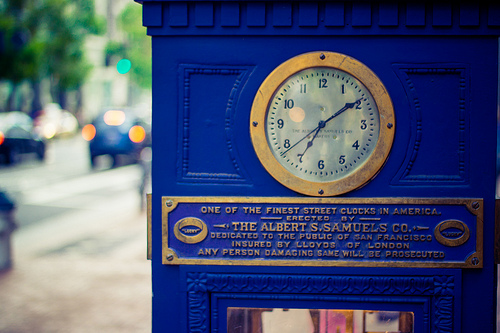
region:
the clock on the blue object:
[248, 50, 393, 195]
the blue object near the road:
[134, 0, 497, 331]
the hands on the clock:
[280, 95, 364, 162]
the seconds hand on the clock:
[281, 121, 320, 154]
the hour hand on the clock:
[301, 127, 323, 155]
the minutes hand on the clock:
[318, 94, 363, 127]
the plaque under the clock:
[161, 193, 485, 268]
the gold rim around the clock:
[248, 50, 395, 196]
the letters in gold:
[196, 203, 446, 260]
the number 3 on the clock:
[359, 117, 367, 129]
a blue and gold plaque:
[159, 193, 489, 270]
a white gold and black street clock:
[247, 47, 399, 197]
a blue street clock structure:
[136, 0, 496, 331]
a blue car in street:
[85, 108, 146, 164]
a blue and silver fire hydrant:
[0, 190, 20, 273]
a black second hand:
[279, 120, 324, 157]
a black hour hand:
[298, 120, 321, 156]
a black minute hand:
[316, 98, 354, 124]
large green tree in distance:
[1, 0, 98, 105]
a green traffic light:
[116, 58, 135, 73]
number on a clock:
[336, 75, 351, 100]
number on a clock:
[352, 110, 375, 132]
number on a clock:
[345, 136, 362, 152]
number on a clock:
[335, 147, 355, 169]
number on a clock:
[313, 148, 331, 183]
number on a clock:
[292, 146, 312, 168]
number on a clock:
[281, 133, 294, 155]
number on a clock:
[270, 111, 293, 131]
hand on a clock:
[318, 91, 358, 124]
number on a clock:
[307, 68, 337, 95]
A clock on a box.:
[265, 66, 380, 182]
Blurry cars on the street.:
[0, 101, 152, 168]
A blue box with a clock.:
[134, 0, 497, 332]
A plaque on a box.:
[161, 195, 485, 270]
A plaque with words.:
[159, 195, 484, 270]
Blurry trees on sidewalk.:
[3, 1, 164, 125]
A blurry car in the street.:
[88, 108, 151, 170]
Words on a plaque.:
[160, 195, 485, 269]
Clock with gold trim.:
[248, 50, 397, 195]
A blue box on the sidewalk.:
[133, 0, 497, 327]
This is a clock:
[240, 39, 435, 200]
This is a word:
[197, 202, 224, 219]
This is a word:
[221, 205, 240, 216]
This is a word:
[240, 200, 261, 217]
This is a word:
[266, 205, 304, 216]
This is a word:
[299, 205, 340, 217]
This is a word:
[338, 203, 380, 218]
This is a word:
[376, 200, 392, 222]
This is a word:
[390, 203, 447, 218]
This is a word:
[224, 216, 260, 233]